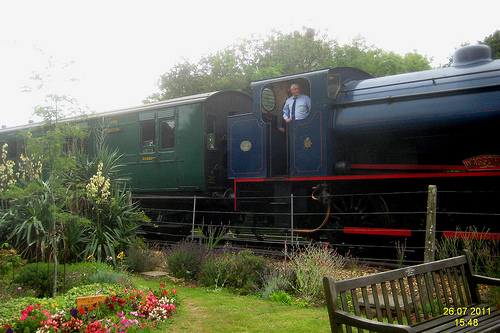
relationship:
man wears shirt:
[283, 83, 311, 122] [282, 98, 314, 123]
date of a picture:
[429, 302, 493, 326] [1, 2, 498, 330]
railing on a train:
[340, 72, 478, 102] [0, 45, 498, 273]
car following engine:
[2, 85, 231, 252] [221, 44, 498, 224]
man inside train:
[281, 79, 314, 131] [147, 56, 470, 246]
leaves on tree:
[246, 46, 304, 86] [152, 24, 430, 101]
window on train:
[158, 118, 174, 149] [0, 45, 498, 273]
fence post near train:
[425, 183, 446, 255] [0, 37, 486, 217]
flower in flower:
[5, 279, 178, 333] [5, 279, 178, 333]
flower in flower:
[77, 298, 108, 305] [5, 279, 178, 333]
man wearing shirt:
[283, 83, 311, 122] [281, 92, 312, 122]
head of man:
[288, 80, 301, 98] [278, 78, 328, 150]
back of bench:
[346, 255, 468, 322] [324, 253, 499, 330]